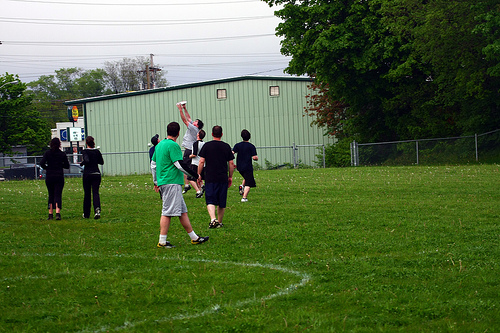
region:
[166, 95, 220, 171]
a man caught the frisbee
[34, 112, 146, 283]
two women are talking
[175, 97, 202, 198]
A person jumping in the air.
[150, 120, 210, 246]
A man in a green shirt.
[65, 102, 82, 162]
A orange and yellow sign.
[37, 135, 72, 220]
A person dressed in black.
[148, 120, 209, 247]
A person wearing white socks.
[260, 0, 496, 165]
A green growing tree.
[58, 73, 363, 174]
A light green building.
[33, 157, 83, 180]
A vehicle in a parking lot.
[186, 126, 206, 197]
A person wearing a white and black shirt.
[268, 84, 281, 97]
A window of a building.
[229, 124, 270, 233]
Person standing in the field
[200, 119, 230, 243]
Person standing in the field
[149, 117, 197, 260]
Person standing in the field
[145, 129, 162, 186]
Person standing in the field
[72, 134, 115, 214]
Person standing in the field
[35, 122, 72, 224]
Person standing in the field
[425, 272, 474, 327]
Small patch of green grass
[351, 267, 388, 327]
Small patch of green grass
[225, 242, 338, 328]
Small patch of green grass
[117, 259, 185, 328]
Small patch of green grass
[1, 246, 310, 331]
circle drawn in grass with spray paint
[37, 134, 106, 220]
two girls hanging out on field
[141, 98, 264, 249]
cluster of boys hanging out on field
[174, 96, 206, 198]
boy jumping into the air to catch the frisbee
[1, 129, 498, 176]
fence surfing the park, creating boundaries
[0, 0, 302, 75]
powerlines that generate electricity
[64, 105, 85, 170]
a pole of advertisements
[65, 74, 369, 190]
building on the opposite side of the fence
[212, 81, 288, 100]
two mini windows on building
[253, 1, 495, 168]
tree that gives shade and oxygen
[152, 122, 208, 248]
guy wearing a green shirt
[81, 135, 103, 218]
woman running in a field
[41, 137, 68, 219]
woman running next to another woman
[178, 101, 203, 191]
man wearing a gray shirt jumping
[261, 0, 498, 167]
big green trees by a field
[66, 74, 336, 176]
gray house by a fiel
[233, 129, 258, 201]
man in black playing in a field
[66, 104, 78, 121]
yellow and red sign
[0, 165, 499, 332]
grass field to play sports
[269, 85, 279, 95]
window on the side of a building